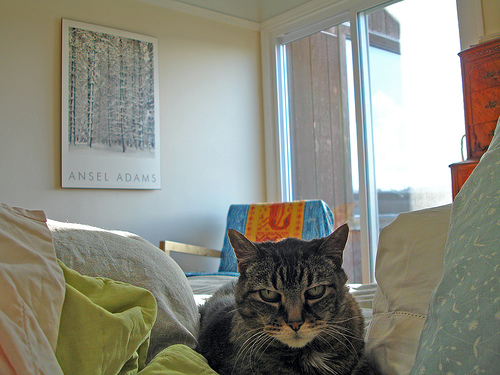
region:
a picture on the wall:
[58, 15, 164, 190]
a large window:
[278, 21, 459, 278]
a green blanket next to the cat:
[58, 273, 188, 372]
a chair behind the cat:
[173, 200, 285, 270]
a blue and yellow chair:
[188, 195, 273, 297]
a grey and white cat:
[197, 224, 379, 365]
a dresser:
[446, 48, 498, 153]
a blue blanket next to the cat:
[418, 168, 498, 321]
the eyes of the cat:
[260, 280, 314, 302]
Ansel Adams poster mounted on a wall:
[54, 13, 164, 194]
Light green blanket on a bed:
[51, 257, 224, 373]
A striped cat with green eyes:
[191, 220, 381, 374]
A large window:
[250, 0, 474, 290]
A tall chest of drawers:
[450, 24, 499, 206]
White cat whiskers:
[224, 304, 372, 372]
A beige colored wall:
[4, 3, 272, 278]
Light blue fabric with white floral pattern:
[404, 112, 496, 372]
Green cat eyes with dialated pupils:
[254, 282, 331, 304]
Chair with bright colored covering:
[160, 199, 339, 311]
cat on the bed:
[194, 227, 389, 374]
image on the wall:
[42, 13, 168, 192]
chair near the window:
[164, 193, 329, 301]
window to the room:
[263, 15, 465, 260]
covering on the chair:
[231, 194, 332, 268]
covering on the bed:
[1, 207, 202, 369]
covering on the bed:
[383, 140, 498, 359]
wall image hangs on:
[1, 5, 262, 248]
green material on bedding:
[72, 287, 137, 354]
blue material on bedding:
[449, 266, 485, 337]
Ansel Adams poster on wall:
[56, 17, 157, 187]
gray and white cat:
[185, 221, 361, 371]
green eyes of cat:
[255, 285, 321, 298]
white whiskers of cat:
[231, 330, 276, 365]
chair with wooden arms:
[160, 196, 332, 301]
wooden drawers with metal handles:
[455, 55, 496, 150]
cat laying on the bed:
[100, 235, 482, 368]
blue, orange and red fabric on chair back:
[230, 204, 340, 256]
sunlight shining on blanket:
[43, 218, 140, 240]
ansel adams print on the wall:
[58, 15, 161, 188]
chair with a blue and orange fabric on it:
[159, 198, 334, 310]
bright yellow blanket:
[53, 259, 215, 374]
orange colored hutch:
[449, 35, 499, 196]